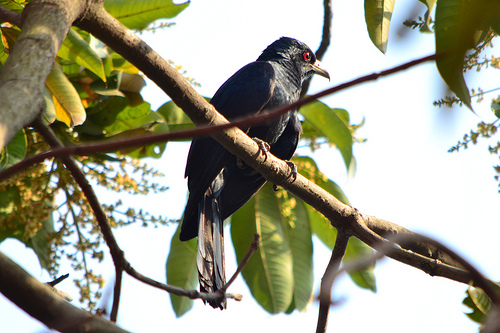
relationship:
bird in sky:
[179, 35, 334, 313] [1, 1, 499, 329]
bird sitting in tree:
[179, 35, 334, 313] [1, 1, 499, 330]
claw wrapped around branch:
[283, 155, 301, 191] [85, 1, 500, 304]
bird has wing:
[179, 35, 334, 313] [183, 62, 278, 197]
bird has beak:
[179, 35, 334, 313] [312, 59, 334, 87]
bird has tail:
[179, 35, 334, 313] [194, 181, 232, 312]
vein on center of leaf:
[249, 188, 279, 315] [231, 177, 297, 317]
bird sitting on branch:
[179, 35, 334, 313] [85, 1, 500, 304]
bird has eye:
[179, 35, 334, 313] [302, 45, 315, 66]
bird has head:
[179, 35, 334, 313] [258, 34, 335, 84]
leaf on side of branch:
[231, 177, 297, 317] [85, 1, 500, 304]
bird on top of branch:
[179, 35, 334, 313] [85, 1, 500, 304]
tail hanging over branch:
[194, 181, 232, 312] [27, 117, 264, 331]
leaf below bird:
[231, 177, 297, 317] [179, 35, 334, 313]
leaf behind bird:
[231, 177, 297, 317] [179, 35, 334, 313]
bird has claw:
[179, 35, 334, 313] [283, 155, 301, 191]